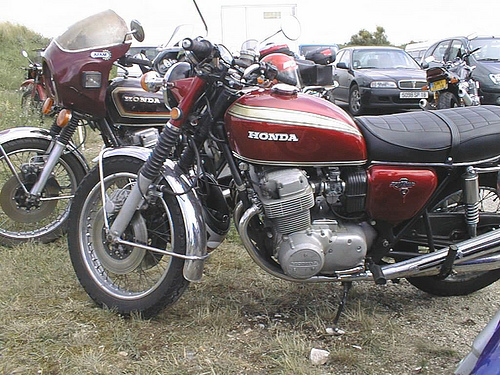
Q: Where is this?
A: This is at the parking lot.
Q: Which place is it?
A: It is a parking lot.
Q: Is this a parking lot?
A: Yes, it is a parking lot.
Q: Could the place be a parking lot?
A: Yes, it is a parking lot.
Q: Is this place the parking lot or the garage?
A: It is the parking lot.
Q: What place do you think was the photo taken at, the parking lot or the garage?
A: It was taken at the parking lot.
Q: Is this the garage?
A: No, it is the parking lot.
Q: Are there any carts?
A: No, there are no carts.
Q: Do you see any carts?
A: No, there are no carts.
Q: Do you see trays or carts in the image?
A: No, there are no carts or trays.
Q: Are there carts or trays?
A: No, there are no carts or trays.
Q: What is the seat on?
A: The seat is on the bike.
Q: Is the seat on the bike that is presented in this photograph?
A: Yes, the seat is on the bike.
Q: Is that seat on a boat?
A: No, the seat is on the bike.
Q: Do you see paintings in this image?
A: No, there are no paintings.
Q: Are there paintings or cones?
A: No, there are no paintings or cones.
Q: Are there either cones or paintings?
A: No, there are no paintings or cones.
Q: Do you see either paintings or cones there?
A: No, there are no paintings or cones.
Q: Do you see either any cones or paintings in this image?
A: No, there are no paintings or cones.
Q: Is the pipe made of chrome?
A: Yes, the pipe is made of chrome.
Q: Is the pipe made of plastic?
A: No, the pipe is made of chrome.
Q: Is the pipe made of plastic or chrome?
A: The pipe is made of chrome.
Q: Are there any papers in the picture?
A: No, there are no papers.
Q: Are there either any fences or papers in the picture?
A: No, there are no papers or fences.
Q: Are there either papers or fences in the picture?
A: No, there are no papers or fences.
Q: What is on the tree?
A: The leaves are on the tree.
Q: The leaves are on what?
A: The leaves are on the tree.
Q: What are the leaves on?
A: The leaves are on the tree.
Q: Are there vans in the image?
A: No, there are no vans.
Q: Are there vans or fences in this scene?
A: No, there are no vans or fences.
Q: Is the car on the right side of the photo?
A: Yes, the car is on the right of the image.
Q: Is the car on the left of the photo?
A: No, the car is on the right of the image.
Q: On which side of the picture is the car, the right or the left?
A: The car is on the right of the image.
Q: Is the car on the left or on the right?
A: The car is on the right of the image.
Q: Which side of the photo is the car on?
A: The car is on the right of the image.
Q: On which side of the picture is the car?
A: The car is on the right of the image.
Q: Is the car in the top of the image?
A: Yes, the car is in the top of the image.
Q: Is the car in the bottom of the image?
A: No, the car is in the top of the image.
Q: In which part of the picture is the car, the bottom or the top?
A: The car is in the top of the image.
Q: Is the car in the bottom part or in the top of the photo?
A: The car is in the top of the image.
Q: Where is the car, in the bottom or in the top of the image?
A: The car is in the top of the image.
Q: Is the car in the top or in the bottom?
A: The car is in the top of the image.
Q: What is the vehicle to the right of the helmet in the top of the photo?
A: The vehicle is a car.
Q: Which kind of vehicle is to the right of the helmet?
A: The vehicle is a car.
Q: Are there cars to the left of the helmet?
A: No, the car is to the right of the helmet.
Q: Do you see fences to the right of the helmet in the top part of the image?
A: No, there is a car to the right of the helmet.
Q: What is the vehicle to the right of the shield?
A: The vehicle is a car.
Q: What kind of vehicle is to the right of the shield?
A: The vehicle is a car.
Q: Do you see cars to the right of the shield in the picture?
A: Yes, there is a car to the right of the shield.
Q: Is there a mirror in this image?
A: Yes, there is a mirror.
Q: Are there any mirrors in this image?
A: Yes, there is a mirror.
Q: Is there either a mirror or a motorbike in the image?
A: Yes, there is a mirror.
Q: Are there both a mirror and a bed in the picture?
A: No, there is a mirror but no beds.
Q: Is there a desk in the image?
A: No, there are no desks.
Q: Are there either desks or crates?
A: No, there are no desks or crates.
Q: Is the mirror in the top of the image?
A: Yes, the mirror is in the top of the image.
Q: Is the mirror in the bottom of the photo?
A: No, the mirror is in the top of the image.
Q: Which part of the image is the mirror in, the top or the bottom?
A: The mirror is in the top of the image.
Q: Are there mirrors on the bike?
A: Yes, there is a mirror on the bike.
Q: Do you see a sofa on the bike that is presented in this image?
A: No, there is a mirror on the bike.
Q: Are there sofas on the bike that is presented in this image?
A: No, there is a mirror on the bike.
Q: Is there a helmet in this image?
A: Yes, there is a helmet.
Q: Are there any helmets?
A: Yes, there is a helmet.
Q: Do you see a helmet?
A: Yes, there is a helmet.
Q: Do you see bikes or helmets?
A: Yes, there is a helmet.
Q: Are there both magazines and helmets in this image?
A: No, there is a helmet but no magazines.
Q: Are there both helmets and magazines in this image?
A: No, there is a helmet but no magazines.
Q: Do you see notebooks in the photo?
A: No, there are no notebooks.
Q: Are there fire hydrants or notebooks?
A: No, there are no notebooks or fire hydrants.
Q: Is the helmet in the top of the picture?
A: Yes, the helmet is in the top of the image.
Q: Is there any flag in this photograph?
A: No, there are no flags.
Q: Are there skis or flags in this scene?
A: No, there are no flags or skis.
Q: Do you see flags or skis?
A: No, there are no flags or skis.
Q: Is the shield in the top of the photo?
A: Yes, the shield is in the top of the image.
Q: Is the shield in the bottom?
A: No, the shield is in the top of the image.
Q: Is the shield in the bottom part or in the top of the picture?
A: The shield is in the top of the image.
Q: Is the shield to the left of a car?
A: Yes, the shield is to the left of a car.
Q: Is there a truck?
A: No, there are no trucks.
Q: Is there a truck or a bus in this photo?
A: No, there are no trucks or buses.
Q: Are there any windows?
A: Yes, there is a window.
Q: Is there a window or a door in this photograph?
A: Yes, there is a window.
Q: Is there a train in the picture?
A: No, there are no trains.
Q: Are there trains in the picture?
A: No, there are no trains.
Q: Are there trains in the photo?
A: No, there are no trains.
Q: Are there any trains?
A: No, there are no trains.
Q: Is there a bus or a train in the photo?
A: No, there are no trains or buses.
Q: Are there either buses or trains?
A: No, there are no trains or buses.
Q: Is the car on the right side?
A: Yes, the car is on the right of the image.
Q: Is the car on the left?
A: No, the car is on the right of the image.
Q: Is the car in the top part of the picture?
A: Yes, the car is in the top of the image.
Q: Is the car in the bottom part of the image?
A: No, the car is in the top of the image.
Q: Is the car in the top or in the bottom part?
A: The car is in the top of the image.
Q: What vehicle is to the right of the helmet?
A: The vehicle is a car.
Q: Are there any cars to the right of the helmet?
A: Yes, there is a car to the right of the helmet.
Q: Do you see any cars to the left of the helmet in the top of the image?
A: No, the car is to the right of the helmet.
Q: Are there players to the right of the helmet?
A: No, there is a car to the right of the helmet.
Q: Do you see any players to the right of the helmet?
A: No, there is a car to the right of the helmet.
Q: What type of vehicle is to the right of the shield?
A: The vehicle is a car.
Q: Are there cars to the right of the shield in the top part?
A: Yes, there is a car to the right of the shield.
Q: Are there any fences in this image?
A: No, there are no fences.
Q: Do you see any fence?
A: No, there are no fences.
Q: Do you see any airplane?
A: No, there are no airplanes.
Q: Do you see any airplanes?
A: No, there are no airplanes.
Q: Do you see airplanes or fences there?
A: No, there are no airplanes or fences.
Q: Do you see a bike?
A: Yes, there is a bike.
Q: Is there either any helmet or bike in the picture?
A: Yes, there is a bike.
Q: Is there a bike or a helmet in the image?
A: Yes, there is a bike.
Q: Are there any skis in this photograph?
A: No, there are no skis.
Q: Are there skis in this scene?
A: No, there are no skis.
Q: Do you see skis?
A: No, there are no skis.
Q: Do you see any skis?
A: No, there are no skis.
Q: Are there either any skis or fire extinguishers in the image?
A: No, there are no skis or fire extinguishers.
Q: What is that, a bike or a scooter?
A: That is a bike.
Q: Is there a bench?
A: No, there are no benches.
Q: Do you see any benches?
A: No, there are no benches.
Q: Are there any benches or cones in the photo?
A: No, there are no benches or cones.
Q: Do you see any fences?
A: No, there are no fences.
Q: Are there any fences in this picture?
A: No, there are no fences.